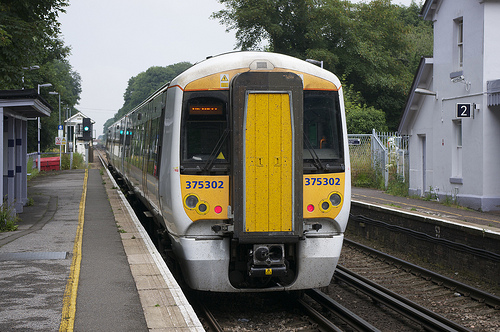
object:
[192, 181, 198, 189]
number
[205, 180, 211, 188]
number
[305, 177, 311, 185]
number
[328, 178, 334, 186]
number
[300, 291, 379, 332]
tracks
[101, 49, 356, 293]
train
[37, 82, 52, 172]
lamp post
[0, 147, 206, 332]
platform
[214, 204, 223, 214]
lamps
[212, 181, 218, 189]
number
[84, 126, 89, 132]
light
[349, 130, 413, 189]
fence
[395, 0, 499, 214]
building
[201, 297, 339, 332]
tracks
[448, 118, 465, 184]
window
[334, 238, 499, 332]
tracks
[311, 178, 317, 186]
numbers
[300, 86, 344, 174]
windows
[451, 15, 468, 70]
window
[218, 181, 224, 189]
number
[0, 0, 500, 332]
city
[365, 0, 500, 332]
right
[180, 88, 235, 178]
window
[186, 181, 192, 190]
number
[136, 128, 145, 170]
passengers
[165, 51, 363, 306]
stop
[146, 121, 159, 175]
passengers